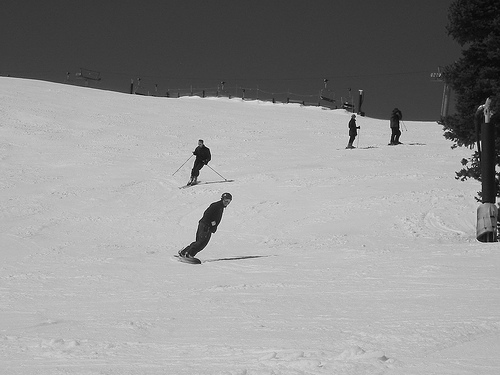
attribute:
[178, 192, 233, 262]
snowboarder — tilted, leaning forward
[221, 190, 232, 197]
helmet — black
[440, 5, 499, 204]
tree — in background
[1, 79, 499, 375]
hill — snow-covered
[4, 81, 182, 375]
snow — white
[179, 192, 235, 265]
man — snowboarding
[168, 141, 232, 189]
man — skiing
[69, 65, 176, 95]
ski lift — in background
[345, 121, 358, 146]
ski suit — black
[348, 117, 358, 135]
jacket — black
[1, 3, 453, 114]
sky — dark, dark grey